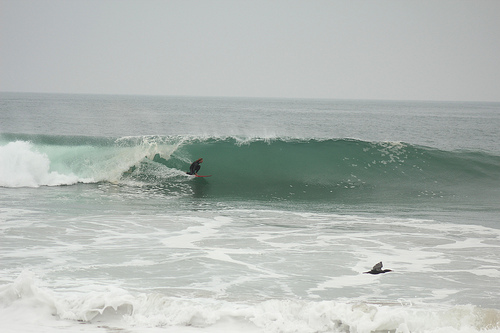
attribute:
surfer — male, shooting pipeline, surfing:
[181, 153, 207, 176]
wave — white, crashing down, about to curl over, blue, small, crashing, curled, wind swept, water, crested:
[1, 132, 500, 209]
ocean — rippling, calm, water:
[1, 94, 500, 330]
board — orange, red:
[184, 173, 211, 178]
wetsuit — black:
[188, 160, 204, 175]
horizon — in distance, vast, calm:
[2, 69, 499, 102]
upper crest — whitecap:
[3, 132, 188, 193]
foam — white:
[1, 142, 95, 192]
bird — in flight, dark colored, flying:
[364, 260, 394, 279]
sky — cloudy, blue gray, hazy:
[3, 3, 499, 104]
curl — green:
[122, 136, 183, 182]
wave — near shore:
[0, 278, 499, 332]